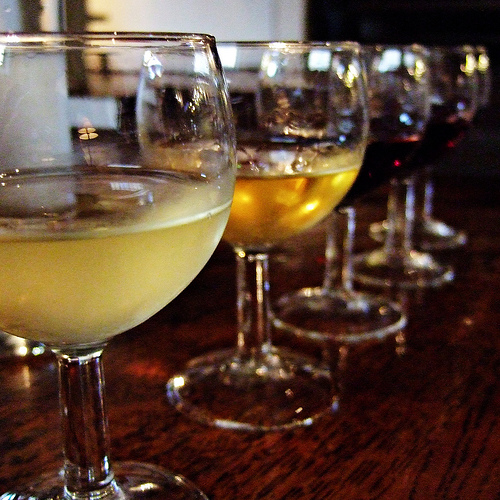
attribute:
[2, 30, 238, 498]
glass — half full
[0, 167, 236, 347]
wine — yellow, white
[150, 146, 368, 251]
wine — dark yellow, white, orange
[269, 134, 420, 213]
wine — purple, red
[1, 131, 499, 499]
table — wooden, dark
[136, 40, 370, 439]
glass — half full, reflective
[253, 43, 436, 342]
glass — half full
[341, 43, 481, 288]
glass — half full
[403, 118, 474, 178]
wine — red